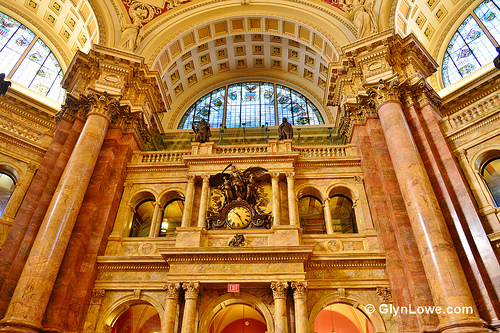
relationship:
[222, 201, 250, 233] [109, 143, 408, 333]
clock on wall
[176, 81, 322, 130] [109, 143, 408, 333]
window are on wall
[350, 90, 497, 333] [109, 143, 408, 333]
column are on wall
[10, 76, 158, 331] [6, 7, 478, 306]
pillar in building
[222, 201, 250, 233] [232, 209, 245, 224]
clock has some arms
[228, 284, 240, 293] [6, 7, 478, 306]
exit in building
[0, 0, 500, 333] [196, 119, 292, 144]
building has a statue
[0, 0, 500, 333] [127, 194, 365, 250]
building has a balcony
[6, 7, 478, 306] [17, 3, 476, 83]
building has a roof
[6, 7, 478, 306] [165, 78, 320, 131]
building has a window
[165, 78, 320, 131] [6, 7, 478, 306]
window in building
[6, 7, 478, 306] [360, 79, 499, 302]
building has a column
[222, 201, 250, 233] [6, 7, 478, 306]
clock in building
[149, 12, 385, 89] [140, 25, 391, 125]
yellow on ceiling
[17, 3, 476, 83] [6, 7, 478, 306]
dome in building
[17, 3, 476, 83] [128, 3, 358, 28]
dome on top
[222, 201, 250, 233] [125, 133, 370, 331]
clock in middle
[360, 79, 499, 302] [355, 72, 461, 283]
column on right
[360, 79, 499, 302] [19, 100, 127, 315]
column on left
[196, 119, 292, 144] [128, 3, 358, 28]
statue on top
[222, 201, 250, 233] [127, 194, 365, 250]
clock on a balcony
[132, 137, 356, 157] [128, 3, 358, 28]
railing on top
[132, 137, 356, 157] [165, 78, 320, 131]
railing under window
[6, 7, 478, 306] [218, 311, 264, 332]
building has a hallway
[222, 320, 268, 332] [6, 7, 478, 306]
entrance into a structure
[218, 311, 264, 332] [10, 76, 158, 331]
hallway has a pillar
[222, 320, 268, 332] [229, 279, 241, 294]
entrance has a exit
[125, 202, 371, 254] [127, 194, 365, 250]
floor has a balcony